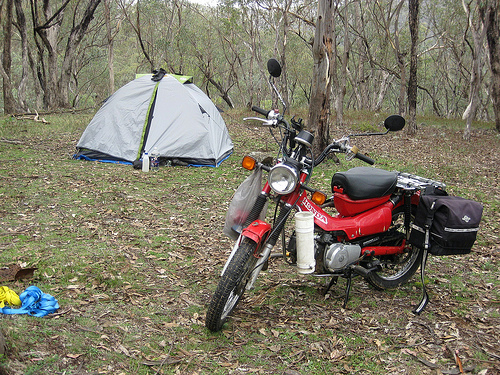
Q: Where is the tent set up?
A: In a camping area.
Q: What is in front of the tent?
A: A red motorcycle.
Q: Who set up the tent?
A: The motorcyclist.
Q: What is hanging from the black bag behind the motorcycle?
A: The bag handle.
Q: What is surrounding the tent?
A: Tall trees.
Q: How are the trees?
A: Dry and leafless.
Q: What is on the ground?
A: Dry fallen leaves.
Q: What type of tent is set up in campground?
A: Dome shaped.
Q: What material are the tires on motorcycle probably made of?
A: Rubber.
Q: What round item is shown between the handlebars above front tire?
A: Headlight.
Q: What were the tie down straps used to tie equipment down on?
A: Motorcycle.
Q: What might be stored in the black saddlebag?
A: Camping supplies.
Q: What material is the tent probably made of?
A: Canvas.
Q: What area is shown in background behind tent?
A: Wooded area.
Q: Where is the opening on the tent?
A: Front middle.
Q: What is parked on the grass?
A: A scooter.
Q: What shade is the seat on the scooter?
A: Black.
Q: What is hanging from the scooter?
A: A plastic bag.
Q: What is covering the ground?
A: Brown leaves.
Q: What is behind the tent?
A: Bare trees.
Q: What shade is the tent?
A: Gray.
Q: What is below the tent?
A: Blue tarp.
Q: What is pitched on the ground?
A: Tent.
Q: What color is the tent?
A: Gray.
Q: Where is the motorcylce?
A: Forest.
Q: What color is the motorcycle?
A: Red.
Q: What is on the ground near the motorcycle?
A: Blue and yellow material.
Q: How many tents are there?
A: One.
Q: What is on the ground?
A: Leaves.